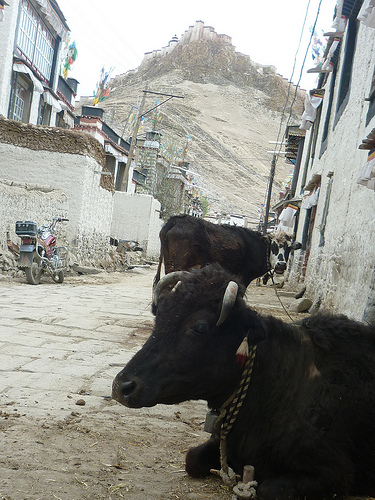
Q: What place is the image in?
A: It is at the road.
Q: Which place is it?
A: It is a road.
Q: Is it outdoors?
A: Yes, it is outdoors.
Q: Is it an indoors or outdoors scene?
A: It is outdoors.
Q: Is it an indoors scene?
A: No, it is outdoors.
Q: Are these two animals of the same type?
A: Yes, all the animals are bulls.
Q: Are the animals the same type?
A: Yes, all the animals are bulls.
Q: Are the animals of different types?
A: No, all the animals are bulls.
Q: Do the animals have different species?
A: No, all the animals are bulls.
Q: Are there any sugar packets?
A: No, there are no sugar packets.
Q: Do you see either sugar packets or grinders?
A: No, there are no sugar packets or grinders.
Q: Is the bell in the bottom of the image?
A: Yes, the bell is in the bottom of the image.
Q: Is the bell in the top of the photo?
A: No, the bell is in the bottom of the image.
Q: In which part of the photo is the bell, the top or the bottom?
A: The bell is in the bottom of the image.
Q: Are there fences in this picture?
A: No, there are no fences.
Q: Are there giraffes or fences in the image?
A: No, there are no fences or giraffes.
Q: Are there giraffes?
A: No, there are no giraffes.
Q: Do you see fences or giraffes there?
A: No, there are no giraffes or fences.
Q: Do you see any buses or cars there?
A: No, there are no cars or buses.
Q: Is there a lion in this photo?
A: No, there are no lions.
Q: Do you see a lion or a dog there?
A: No, there are no lions or dogs.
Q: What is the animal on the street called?
A: The animal is a bull.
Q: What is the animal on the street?
A: The animal is a bull.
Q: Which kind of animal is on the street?
A: The animal is a bull.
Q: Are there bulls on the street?
A: Yes, there is a bull on the street.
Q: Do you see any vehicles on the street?
A: No, there is a bull on the street.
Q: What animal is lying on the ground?
A: The bull is lying on the ground.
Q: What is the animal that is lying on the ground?
A: The animal is a bull.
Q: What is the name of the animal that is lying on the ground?
A: The animal is a bull.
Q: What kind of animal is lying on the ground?
A: The animal is a bull.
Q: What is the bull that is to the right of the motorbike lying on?
A: The bull is lying on the ground.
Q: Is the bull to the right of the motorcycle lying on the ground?
A: Yes, the bull is lying on the ground.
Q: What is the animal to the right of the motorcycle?
A: The animal is a bull.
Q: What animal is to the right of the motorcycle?
A: The animal is a bull.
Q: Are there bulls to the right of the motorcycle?
A: Yes, there is a bull to the right of the motorcycle.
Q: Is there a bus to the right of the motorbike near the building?
A: No, there is a bull to the right of the motorcycle.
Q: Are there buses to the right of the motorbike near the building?
A: No, there is a bull to the right of the motorcycle.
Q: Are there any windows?
A: Yes, there is a window.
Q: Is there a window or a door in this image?
A: Yes, there is a window.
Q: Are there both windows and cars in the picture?
A: No, there is a window but no cars.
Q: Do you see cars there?
A: No, there are no cars.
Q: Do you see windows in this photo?
A: Yes, there is a window.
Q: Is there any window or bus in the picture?
A: Yes, there is a window.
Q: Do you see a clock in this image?
A: No, there are no clocks.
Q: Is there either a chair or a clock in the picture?
A: No, there are no clocks or chairs.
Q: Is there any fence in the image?
A: No, there are no fences.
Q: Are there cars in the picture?
A: No, there are no cars.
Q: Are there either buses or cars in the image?
A: No, there are no cars or buses.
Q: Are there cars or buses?
A: No, there are no cars or buses.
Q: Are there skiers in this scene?
A: No, there are no skiers.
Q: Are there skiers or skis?
A: No, there are no skiers or skis.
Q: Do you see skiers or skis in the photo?
A: No, there are no skiers or skis.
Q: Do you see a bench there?
A: No, there are no benches.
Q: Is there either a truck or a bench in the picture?
A: No, there are no benches or trucks.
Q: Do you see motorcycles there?
A: Yes, there is a motorcycle.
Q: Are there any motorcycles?
A: Yes, there is a motorcycle.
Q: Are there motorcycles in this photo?
A: Yes, there is a motorcycle.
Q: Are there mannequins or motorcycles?
A: Yes, there is a motorcycle.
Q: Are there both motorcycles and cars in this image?
A: No, there is a motorcycle but no cars.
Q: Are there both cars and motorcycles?
A: No, there is a motorcycle but no cars.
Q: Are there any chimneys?
A: No, there are no chimneys.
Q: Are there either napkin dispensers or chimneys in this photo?
A: No, there are no chimneys or napkin dispensers.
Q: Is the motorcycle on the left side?
A: Yes, the motorcycle is on the left of the image.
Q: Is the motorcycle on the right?
A: No, the motorcycle is on the left of the image.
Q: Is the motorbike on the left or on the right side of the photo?
A: The motorbike is on the left of the image.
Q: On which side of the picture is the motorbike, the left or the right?
A: The motorbike is on the left of the image.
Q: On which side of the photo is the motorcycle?
A: The motorcycle is on the left of the image.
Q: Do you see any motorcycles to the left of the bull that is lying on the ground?
A: Yes, there is a motorcycle to the left of the bull.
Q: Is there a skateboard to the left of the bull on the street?
A: No, there is a motorcycle to the left of the bull.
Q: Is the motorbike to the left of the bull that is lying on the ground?
A: Yes, the motorbike is to the left of the bull.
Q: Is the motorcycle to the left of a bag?
A: No, the motorcycle is to the left of the bull.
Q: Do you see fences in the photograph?
A: No, there are no fences.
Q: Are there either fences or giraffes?
A: No, there are no fences or giraffes.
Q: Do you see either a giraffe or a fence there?
A: No, there are no fences or giraffes.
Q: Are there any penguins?
A: No, there are no penguins.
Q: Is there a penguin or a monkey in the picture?
A: No, there are no penguins or monkeys.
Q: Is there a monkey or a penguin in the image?
A: No, there are no penguins or monkeys.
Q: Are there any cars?
A: No, there are no cars.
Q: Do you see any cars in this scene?
A: No, there are no cars.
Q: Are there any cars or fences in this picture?
A: No, there are no cars or fences.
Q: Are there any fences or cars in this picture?
A: No, there are no cars or fences.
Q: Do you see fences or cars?
A: No, there are no cars or fences.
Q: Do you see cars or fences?
A: No, there are no cars or fences.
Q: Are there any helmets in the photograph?
A: No, there are no helmets.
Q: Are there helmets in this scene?
A: No, there are no helmets.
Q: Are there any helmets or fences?
A: No, there are no helmets or fences.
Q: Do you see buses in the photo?
A: No, there are no buses.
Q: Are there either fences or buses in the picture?
A: No, there are no buses or fences.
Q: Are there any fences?
A: No, there are no fences.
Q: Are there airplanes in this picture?
A: No, there are no airplanes.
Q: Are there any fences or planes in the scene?
A: No, there are no planes or fences.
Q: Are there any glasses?
A: No, there are no glasses.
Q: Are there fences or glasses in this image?
A: No, there are no glasses or fences.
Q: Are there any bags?
A: No, there are no bags.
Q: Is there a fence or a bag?
A: No, there are no bags or fences.